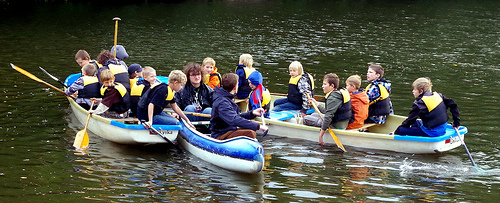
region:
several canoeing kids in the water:
[7, 10, 490, 188]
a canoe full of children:
[263, 54, 481, 160]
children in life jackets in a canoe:
[265, 57, 480, 167]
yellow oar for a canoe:
[67, 99, 107, 162]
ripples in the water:
[260, 20, 365, 50]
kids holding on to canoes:
[31, 31, 291, 178]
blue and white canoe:
[168, 60, 270, 182]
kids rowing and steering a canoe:
[256, 49, 485, 171]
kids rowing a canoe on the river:
[36, 29, 181, 154]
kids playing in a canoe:
[26, 20, 183, 160]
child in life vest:
[376, 58, 443, 172]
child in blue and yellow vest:
[356, 65, 457, 195]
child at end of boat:
[382, 56, 477, 180]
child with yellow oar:
[72, 62, 128, 157]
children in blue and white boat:
[255, 66, 448, 200]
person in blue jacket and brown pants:
[206, 73, 246, 150]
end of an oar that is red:
[253, 61, 275, 155]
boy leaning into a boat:
[122, 51, 214, 176]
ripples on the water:
[288, 10, 407, 45]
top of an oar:
[97, 4, 132, 62]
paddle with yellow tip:
[9, 55, 75, 110]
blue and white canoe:
[179, 88, 292, 195]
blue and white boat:
[270, 69, 499, 166]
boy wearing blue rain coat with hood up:
[239, 66, 278, 118]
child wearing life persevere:
[276, 51, 316, 116]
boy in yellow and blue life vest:
[402, 74, 450, 155]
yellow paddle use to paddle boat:
[301, 87, 363, 183]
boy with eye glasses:
[183, 59, 213, 89]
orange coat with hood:
[344, 87, 386, 144]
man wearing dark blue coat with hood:
[212, 84, 269, 156]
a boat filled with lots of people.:
[46, 33, 180, 170]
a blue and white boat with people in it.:
[220, 37, 468, 169]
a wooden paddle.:
[297, 53, 352, 173]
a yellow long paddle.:
[60, 58, 117, 158]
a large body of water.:
[3, 5, 497, 201]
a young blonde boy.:
[140, 56, 170, 117]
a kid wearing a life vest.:
[385, 70, 460, 151]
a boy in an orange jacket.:
[335, 70, 374, 147]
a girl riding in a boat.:
[277, 63, 335, 130]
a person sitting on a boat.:
[232, 56, 278, 156]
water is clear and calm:
[21, 142, 108, 201]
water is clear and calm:
[42, 152, 77, 194]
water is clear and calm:
[72, 136, 140, 197]